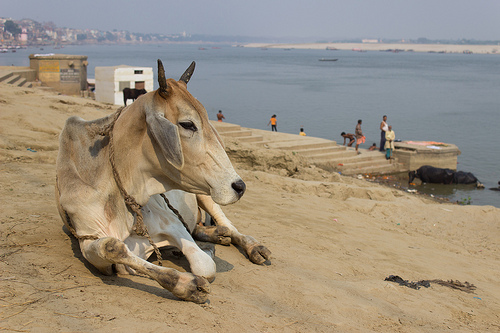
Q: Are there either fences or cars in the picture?
A: No, there are no fences or cars.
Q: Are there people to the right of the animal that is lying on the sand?
A: Yes, there is a person to the right of the animal.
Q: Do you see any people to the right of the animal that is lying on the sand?
A: Yes, there is a person to the right of the animal.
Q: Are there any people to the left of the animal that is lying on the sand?
A: No, the person is to the right of the animal.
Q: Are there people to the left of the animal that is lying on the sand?
A: No, the person is to the right of the animal.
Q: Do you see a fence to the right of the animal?
A: No, there is a person to the right of the animal.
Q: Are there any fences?
A: No, there are no fences.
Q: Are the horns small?
A: Yes, the horns are small.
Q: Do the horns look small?
A: Yes, the horns are small.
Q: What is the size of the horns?
A: The horns are small.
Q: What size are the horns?
A: The horns are small.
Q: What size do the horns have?
A: The horns have small size.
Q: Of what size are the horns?
A: The horns are small.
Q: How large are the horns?
A: The horns are small.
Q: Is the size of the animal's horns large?
A: No, the horns are small.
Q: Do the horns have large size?
A: No, the horns are small.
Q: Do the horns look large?
A: No, the horns are small.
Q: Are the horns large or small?
A: The horns are small.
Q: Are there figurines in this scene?
A: No, there are no figurines.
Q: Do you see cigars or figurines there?
A: No, there are no figurines or cigars.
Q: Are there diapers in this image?
A: No, there are no diapers.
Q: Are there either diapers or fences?
A: No, there are no diapers or fences.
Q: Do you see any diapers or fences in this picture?
A: No, there are no diapers or fences.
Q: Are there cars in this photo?
A: No, there are no cars.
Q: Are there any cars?
A: No, there are no cars.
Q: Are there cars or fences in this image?
A: No, there are no cars or fences.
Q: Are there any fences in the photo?
A: No, there are no fences.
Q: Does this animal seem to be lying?
A: Yes, the animal is lying.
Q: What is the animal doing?
A: The animal is lying.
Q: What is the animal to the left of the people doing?
A: The animal is lying.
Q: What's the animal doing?
A: The animal is lying.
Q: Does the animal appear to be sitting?
A: No, the animal is lying.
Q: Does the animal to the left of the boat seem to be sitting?
A: No, the animal is lying.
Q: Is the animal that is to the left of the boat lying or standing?
A: The animal is lying.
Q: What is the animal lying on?
A: The animal is lying on the sand.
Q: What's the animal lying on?
A: The animal is lying on the sand.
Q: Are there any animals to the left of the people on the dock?
A: Yes, there is an animal to the left of the people.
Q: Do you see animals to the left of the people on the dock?
A: Yes, there is an animal to the left of the people.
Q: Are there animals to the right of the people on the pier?
A: No, the animal is to the left of the people.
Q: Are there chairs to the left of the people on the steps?
A: No, there is an animal to the left of the people.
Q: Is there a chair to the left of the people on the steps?
A: No, there is an animal to the left of the people.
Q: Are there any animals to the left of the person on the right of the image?
A: Yes, there is an animal to the left of the person.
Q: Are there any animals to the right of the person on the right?
A: No, the animal is to the left of the person.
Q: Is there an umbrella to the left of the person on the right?
A: No, there is an animal to the left of the person.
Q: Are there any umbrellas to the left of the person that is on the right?
A: No, there is an animal to the left of the person.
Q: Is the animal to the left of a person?
A: Yes, the animal is to the left of a person.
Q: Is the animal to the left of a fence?
A: No, the animal is to the left of a person.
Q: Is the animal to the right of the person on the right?
A: No, the animal is to the left of the person.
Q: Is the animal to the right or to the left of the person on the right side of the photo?
A: The animal is to the left of the person.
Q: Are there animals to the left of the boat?
A: Yes, there is an animal to the left of the boat.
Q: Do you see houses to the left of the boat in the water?
A: No, there is an animal to the left of the boat.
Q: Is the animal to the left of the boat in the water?
A: Yes, the animal is to the left of the boat.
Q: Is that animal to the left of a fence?
A: No, the animal is to the left of the boat.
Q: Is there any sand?
A: Yes, there is sand.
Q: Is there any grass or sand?
A: Yes, there is sand.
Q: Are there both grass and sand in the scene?
A: No, there is sand but no grass.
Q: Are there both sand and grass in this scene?
A: No, there is sand but no grass.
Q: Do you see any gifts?
A: No, there are no gifts.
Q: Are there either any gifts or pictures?
A: No, there are no gifts or pictures.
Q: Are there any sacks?
A: No, there are no sacks.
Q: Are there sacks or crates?
A: No, there are no sacks or crates.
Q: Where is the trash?
A: The trash is in the water.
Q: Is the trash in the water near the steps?
A: Yes, the trash is in the water.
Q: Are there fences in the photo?
A: No, there are no fences.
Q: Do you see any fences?
A: No, there are no fences.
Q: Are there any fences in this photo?
A: No, there are no fences.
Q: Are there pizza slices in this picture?
A: No, there are no pizza slices.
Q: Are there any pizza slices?
A: No, there are no pizza slices.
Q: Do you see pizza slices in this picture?
A: No, there are no pizza slices.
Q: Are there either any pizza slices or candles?
A: No, there are no pizza slices or candles.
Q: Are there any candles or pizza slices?
A: No, there are no pizza slices or candles.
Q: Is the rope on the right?
A: No, the rope is on the left of the image.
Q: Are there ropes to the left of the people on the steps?
A: Yes, there is a rope to the left of the people.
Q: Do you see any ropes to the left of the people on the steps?
A: Yes, there is a rope to the left of the people.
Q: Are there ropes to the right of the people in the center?
A: No, the rope is to the left of the people.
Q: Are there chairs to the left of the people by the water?
A: No, there is a rope to the left of the people.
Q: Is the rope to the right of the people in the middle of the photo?
A: No, the rope is to the left of the people.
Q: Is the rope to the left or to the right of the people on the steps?
A: The rope is to the left of the people.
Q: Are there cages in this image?
A: No, there are no cages.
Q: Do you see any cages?
A: No, there are no cages.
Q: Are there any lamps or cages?
A: No, there are no cages or lamps.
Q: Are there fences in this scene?
A: No, there are no fences.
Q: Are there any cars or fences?
A: No, there are no fences or cars.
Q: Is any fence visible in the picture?
A: No, there are no fences.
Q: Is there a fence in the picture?
A: No, there are no fences.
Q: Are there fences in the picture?
A: No, there are no fences.